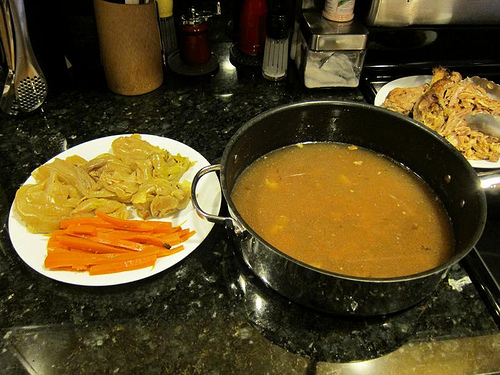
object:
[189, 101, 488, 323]
pot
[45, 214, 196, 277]
carrots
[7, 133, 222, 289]
plate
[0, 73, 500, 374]
counter top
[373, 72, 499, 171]
plate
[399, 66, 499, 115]
chicken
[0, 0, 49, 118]
utensils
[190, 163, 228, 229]
handle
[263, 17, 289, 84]
shaker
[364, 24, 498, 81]
stove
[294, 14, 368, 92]
container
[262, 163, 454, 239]
broth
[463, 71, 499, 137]
tongs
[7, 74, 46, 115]
holes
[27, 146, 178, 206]
cabbage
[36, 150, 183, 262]
food